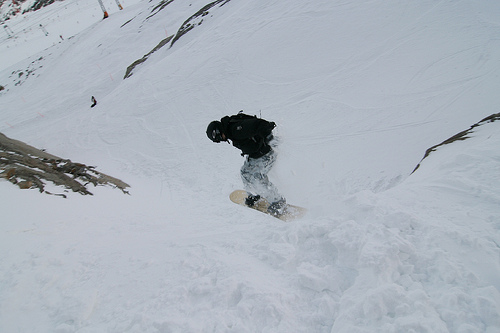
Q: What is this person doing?
A: Snowboarding.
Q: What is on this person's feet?
A: A snowboard.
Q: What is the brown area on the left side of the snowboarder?
A: Rocks sticking out of the snow.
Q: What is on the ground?
A: Snow.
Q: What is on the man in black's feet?
A: A snowboard.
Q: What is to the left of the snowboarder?
A: A stretch of stone face.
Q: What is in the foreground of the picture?
A: Snow on a cliff side.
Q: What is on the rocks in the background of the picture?
A: Snow is covering the rocks.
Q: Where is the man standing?
A: In snow.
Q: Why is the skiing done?
A: Fun.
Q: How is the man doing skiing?
A: In snow.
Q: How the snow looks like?
A: White.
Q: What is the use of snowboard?
A: Skiing.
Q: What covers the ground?
A: Snow.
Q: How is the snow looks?
A: Not smooth.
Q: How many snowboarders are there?
A: One.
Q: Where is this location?
A: Hillside.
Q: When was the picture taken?
A: Daytime.